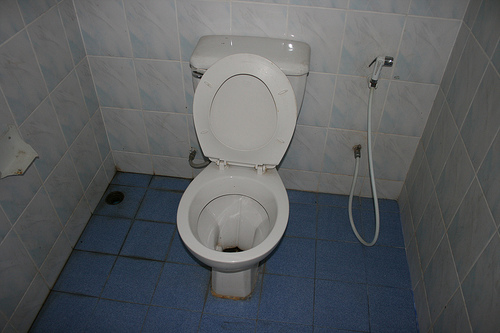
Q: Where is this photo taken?
A: A bathroom.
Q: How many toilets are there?
A: One.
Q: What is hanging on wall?
A: A hose.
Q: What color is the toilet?
A: White.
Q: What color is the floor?
A: Blue.